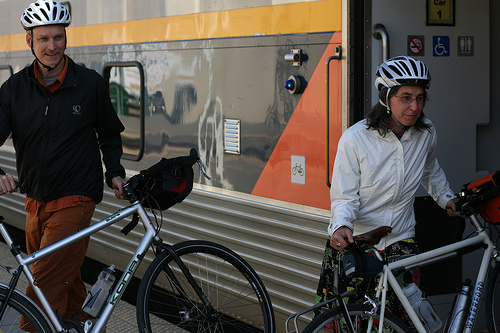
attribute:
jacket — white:
[318, 125, 448, 218]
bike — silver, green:
[24, 204, 238, 311]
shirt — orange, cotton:
[0, 58, 125, 215]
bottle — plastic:
[81, 263, 120, 318]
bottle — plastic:
[399, 280, 445, 331]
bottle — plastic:
[438, 281, 466, 331]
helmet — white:
[369, 50, 436, 106]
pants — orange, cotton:
[18, 196, 98, 331]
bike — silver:
[296, 190, 494, 332]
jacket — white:
[323, 106, 460, 246]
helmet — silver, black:
[377, 50, 429, 114]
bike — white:
[282, 172, 498, 329]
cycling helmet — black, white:
[373, 55, 433, 89]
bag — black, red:
[123, 147, 203, 211]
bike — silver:
[2, 159, 289, 330]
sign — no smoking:
[407, 34, 423, 56]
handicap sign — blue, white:
[432, 31, 455, 58]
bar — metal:
[320, 52, 331, 181]